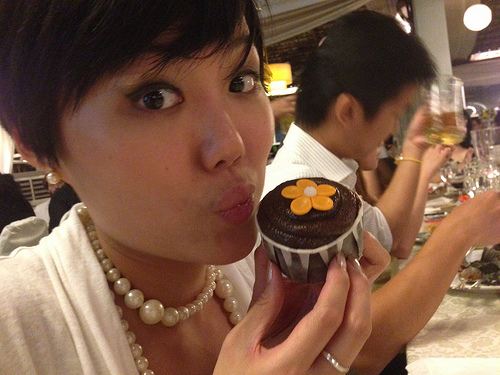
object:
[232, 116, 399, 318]
shirt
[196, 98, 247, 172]
nose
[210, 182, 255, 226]
lips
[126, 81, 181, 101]
eye shadow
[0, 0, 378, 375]
people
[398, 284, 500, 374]
table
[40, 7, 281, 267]
face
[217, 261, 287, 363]
thumb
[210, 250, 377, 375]
hand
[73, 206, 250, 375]
necklace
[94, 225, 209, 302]
neck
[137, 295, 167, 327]
pearl necklaces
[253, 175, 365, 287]
cake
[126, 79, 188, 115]
eye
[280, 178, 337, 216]
flower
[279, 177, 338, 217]
frosting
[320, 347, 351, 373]
ring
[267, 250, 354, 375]
finger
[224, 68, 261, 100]
eye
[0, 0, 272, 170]
hair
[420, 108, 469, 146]
mug beer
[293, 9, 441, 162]
head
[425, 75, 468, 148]
glass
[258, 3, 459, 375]
man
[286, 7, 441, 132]
brown hair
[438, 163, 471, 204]
beer